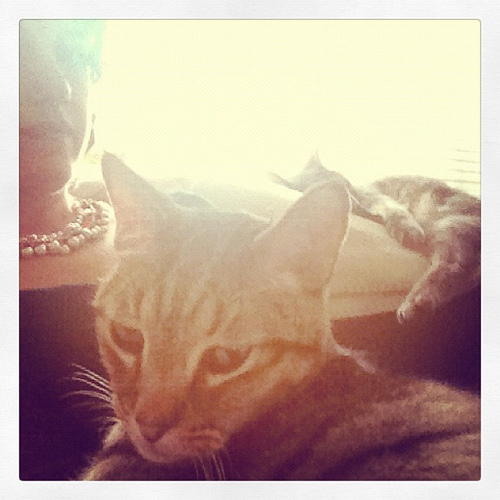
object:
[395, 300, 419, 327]
paw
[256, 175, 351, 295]
ear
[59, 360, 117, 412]
whiskers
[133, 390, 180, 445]
nose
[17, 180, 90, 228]
neck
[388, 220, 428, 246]
paws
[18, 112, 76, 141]
mouth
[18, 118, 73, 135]
lips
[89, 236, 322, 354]
forehead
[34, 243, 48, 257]
pearls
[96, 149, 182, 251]
ears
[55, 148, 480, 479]
cat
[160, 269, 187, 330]
stripes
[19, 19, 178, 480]
woman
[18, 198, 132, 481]
body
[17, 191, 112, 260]
necklace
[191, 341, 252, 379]
cat eyes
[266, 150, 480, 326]
cat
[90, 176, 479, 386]
furniture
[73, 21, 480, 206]
sun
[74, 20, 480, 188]
window